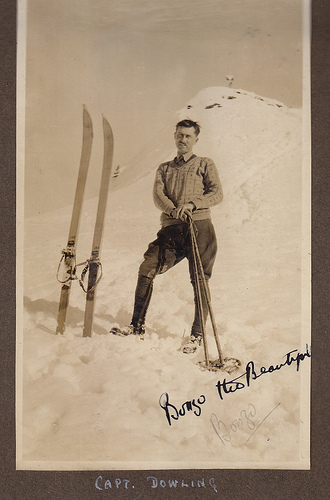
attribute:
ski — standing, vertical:
[80, 108, 115, 335]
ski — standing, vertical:
[51, 102, 96, 334]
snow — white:
[39, 313, 276, 447]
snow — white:
[130, 401, 132, 407]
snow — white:
[43, 326, 215, 422]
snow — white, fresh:
[23, 85, 302, 463]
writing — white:
[91, 471, 223, 495]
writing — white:
[159, 340, 311, 447]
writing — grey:
[116, 324, 319, 418]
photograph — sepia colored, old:
[60, 79, 263, 335]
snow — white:
[25, 218, 301, 461]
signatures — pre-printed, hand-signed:
[152, 334, 316, 457]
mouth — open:
[177, 140, 187, 146]